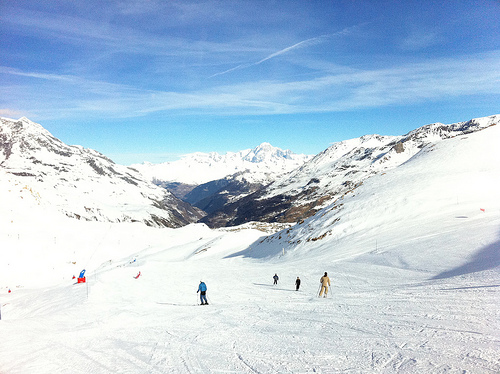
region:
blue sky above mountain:
[158, 98, 445, 208]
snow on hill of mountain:
[358, 199, 497, 302]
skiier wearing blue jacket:
[176, 275, 229, 334]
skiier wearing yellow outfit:
[312, 260, 369, 317]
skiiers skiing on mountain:
[36, 238, 410, 325]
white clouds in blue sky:
[97, 26, 384, 126]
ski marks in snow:
[358, 288, 490, 372]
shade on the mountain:
[153, 174, 292, 229]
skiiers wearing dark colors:
[257, 266, 311, 322]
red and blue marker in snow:
[53, 251, 122, 287]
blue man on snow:
[172, 275, 227, 312]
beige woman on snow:
[304, 249, 341, 296]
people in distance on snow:
[249, 242, 307, 295]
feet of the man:
[198, 297, 214, 310]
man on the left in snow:
[63, 252, 114, 294]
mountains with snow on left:
[14, 106, 258, 260]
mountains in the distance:
[204, 105, 370, 222]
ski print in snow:
[230, 285, 298, 372]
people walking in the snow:
[45, 227, 380, 329]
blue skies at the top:
[82, 59, 392, 149]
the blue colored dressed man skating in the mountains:
[182, 266, 214, 315]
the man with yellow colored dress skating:
[311, 269, 346, 310]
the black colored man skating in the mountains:
[284, 270, 311, 301]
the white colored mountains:
[361, 172, 433, 272]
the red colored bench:
[67, 261, 94, 289]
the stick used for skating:
[312, 282, 322, 291]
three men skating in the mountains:
[263, 258, 343, 305]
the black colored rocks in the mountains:
[196, 186, 287, 238]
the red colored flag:
[120, 265, 164, 286]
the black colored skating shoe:
[196, 298, 212, 308]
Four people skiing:
[179, 264, 342, 301]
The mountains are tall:
[1, 113, 497, 248]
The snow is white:
[146, 282, 496, 366]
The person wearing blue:
[196, 279, 216, 310]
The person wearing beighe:
[316, 272, 338, 295]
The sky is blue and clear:
[61, 35, 373, 137]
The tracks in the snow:
[183, 328, 495, 372]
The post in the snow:
[82, 280, 92, 310]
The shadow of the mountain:
[223, 220, 313, 256]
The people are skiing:
[194, 265, 350, 320]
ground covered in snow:
[430, 154, 498, 196]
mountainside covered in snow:
[0, 122, 102, 229]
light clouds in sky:
[224, 69, 431, 116]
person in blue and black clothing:
[189, 271, 219, 312]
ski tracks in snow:
[371, 336, 440, 373]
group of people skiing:
[264, 266, 356, 308]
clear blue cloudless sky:
[389, 2, 425, 27]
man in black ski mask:
[318, 268, 332, 275]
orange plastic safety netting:
[126, 265, 153, 282]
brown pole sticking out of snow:
[82, 281, 92, 298]